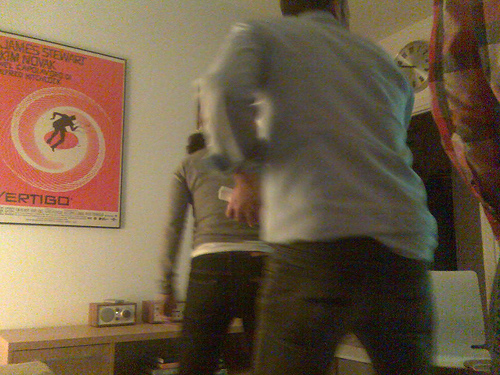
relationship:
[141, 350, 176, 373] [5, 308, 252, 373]
books on shelf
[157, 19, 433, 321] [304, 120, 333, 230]
man wearing a grey shirt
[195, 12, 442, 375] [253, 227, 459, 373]
man wears pants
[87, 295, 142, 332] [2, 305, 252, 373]
speaker on desk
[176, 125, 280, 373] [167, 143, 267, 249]
man with sweater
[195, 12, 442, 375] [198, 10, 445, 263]
man in shirt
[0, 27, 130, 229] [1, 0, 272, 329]
picture hanging on a wall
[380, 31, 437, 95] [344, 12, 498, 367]
clock hanging on wall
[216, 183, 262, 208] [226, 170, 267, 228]
controller in hand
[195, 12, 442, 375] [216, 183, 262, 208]
man holding controller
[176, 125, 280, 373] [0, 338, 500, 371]
man standing on floor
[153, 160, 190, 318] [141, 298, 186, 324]
arm on radio